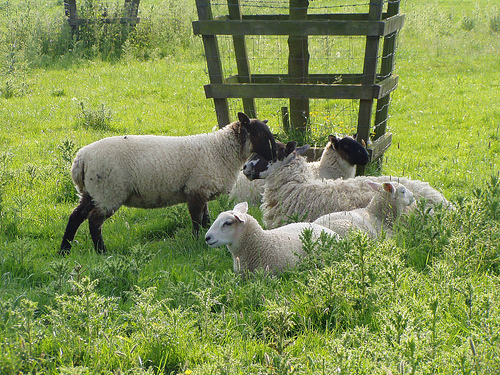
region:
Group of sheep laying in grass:
[61, 112, 462, 274]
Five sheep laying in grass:
[57, 112, 463, 278]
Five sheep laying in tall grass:
[58, 110, 463, 275]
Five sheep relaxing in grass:
[58, 110, 460, 281]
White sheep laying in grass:
[204, 200, 339, 278]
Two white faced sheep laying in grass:
[203, 178, 413, 275]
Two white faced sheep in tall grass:
[203, 178, 413, 275]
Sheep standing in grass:
[59, 112, 278, 254]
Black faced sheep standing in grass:
[58, 113, 276, 254]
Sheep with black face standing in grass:
[58, 112, 278, 257]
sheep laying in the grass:
[236, 138, 464, 320]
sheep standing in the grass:
[25, 90, 280, 242]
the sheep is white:
[162, 192, 347, 274]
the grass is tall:
[259, 214, 451, 353]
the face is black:
[218, 99, 283, 174]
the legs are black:
[47, 193, 118, 258]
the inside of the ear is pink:
[367, 176, 397, 198]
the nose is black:
[199, 228, 215, 245]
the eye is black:
[208, 212, 238, 232]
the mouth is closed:
[187, 232, 222, 254]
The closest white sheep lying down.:
[201, 202, 342, 276]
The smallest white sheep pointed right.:
[314, 181, 418, 245]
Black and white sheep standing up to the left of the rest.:
[59, 112, 282, 255]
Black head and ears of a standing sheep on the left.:
[236, 110, 280, 162]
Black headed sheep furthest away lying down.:
[227, 135, 371, 200]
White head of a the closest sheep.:
[203, 201, 252, 247]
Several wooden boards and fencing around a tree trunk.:
[190, 1, 402, 173]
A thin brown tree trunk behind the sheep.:
[284, 0, 311, 143]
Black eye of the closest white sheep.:
[221, 218, 235, 228]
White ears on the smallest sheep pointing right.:
[366, 178, 395, 195]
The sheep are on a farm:
[20, 25, 472, 350]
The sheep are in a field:
[10, 30, 465, 360]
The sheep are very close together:
[5, 60, 475, 365]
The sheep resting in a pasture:
[5, 55, 485, 350]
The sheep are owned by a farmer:
[10, 55, 480, 365]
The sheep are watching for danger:
[5, 21, 462, 371]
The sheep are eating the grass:
[31, 46, 452, 366]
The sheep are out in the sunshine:
[10, 60, 480, 345]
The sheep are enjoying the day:
[35, 67, 470, 372]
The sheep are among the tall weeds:
[28, 11, 478, 373]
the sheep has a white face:
[203, 199, 266, 260]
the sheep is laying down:
[197, 201, 357, 272]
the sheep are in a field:
[51, 100, 476, 317]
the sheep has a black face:
[233, 113, 282, 165]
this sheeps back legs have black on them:
[58, 187, 119, 264]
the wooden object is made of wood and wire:
[188, 2, 393, 176]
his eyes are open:
[221, 220, 235, 230]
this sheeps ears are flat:
[228, 211, 248, 231]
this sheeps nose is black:
[201, 234, 214, 244]